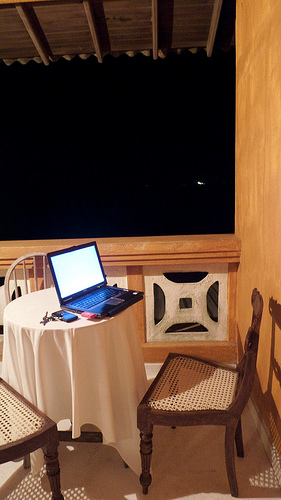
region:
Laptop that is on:
[38, 241, 147, 324]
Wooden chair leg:
[124, 400, 161, 495]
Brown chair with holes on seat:
[131, 288, 265, 496]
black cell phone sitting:
[51, 309, 80, 329]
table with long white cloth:
[2, 290, 164, 463]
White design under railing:
[135, 254, 244, 352]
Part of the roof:
[4, 17, 219, 68]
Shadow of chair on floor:
[3, 461, 140, 498]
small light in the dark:
[147, 143, 234, 230]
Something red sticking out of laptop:
[81, 308, 99, 325]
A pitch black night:
[8, 36, 262, 266]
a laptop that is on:
[43, 250, 149, 318]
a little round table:
[4, 282, 158, 447]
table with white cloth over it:
[3, 285, 161, 471]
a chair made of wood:
[136, 287, 267, 492]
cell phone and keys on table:
[35, 304, 81, 335]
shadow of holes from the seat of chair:
[3, 391, 65, 498]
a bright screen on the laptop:
[46, 239, 115, 291]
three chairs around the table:
[0, 244, 268, 469]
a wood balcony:
[0, 222, 253, 342]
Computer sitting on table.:
[47, 239, 148, 319]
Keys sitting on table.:
[37, 310, 52, 329]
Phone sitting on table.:
[51, 308, 79, 324]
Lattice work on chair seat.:
[175, 364, 223, 406]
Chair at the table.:
[132, 282, 268, 498]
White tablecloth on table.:
[54, 331, 136, 475]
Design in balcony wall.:
[140, 267, 239, 346]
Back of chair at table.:
[232, 285, 260, 417]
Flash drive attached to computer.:
[79, 311, 98, 319]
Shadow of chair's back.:
[261, 286, 279, 437]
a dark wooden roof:
[1, 3, 212, 45]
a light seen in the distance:
[192, 175, 208, 190]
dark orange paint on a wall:
[242, 191, 272, 261]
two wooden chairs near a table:
[0, 290, 263, 499]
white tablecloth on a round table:
[5, 290, 138, 391]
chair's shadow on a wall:
[265, 292, 279, 420]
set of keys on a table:
[36, 307, 52, 328]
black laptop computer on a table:
[47, 238, 139, 308]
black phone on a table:
[52, 307, 77, 325]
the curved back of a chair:
[3, 250, 48, 289]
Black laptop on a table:
[43, 240, 148, 320]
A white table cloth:
[11, 299, 146, 431]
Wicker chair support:
[157, 350, 237, 422]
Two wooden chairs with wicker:
[1, 336, 259, 471]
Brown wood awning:
[0, 0, 227, 68]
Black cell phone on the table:
[47, 306, 80, 321]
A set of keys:
[34, 309, 57, 328]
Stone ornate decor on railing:
[139, 261, 229, 341]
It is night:
[10, 58, 223, 219]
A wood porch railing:
[7, 235, 240, 362]